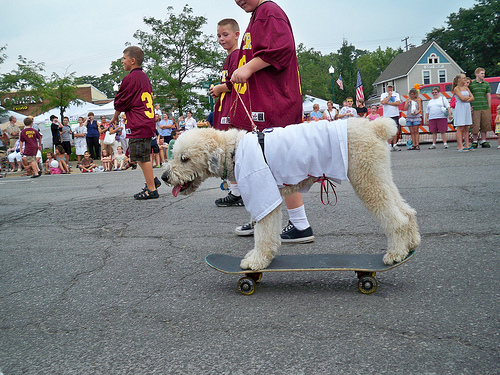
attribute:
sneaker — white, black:
[235, 218, 257, 235]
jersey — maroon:
[114, 66, 166, 147]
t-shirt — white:
[233, 118, 346, 222]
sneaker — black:
[281, 220, 315, 241]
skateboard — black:
[202, 245, 418, 298]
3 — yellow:
[139, 88, 155, 122]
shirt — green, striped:
[468, 77, 495, 112]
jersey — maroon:
[112, 67, 155, 141]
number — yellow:
[138, 92, 153, 119]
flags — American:
[338, 70, 366, 104]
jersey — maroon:
[113, 68, 155, 134]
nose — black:
[146, 161, 177, 183]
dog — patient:
[138, 117, 463, 277]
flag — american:
[354, 70, 366, 109]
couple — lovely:
[453, 62, 494, 156]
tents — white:
[41, 81, 133, 159]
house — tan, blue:
[367, 42, 468, 139]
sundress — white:
[454, 90, 474, 128]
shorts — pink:
[426, 118, 446, 134]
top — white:
[428, 97, 449, 120]